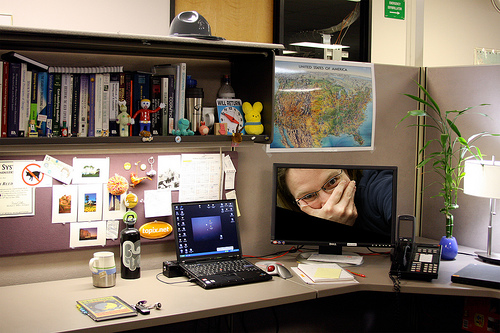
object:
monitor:
[271, 163, 397, 248]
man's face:
[286, 169, 355, 217]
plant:
[395, 77, 499, 235]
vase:
[438, 237, 458, 261]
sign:
[385, 1, 404, 20]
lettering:
[388, 2, 401, 17]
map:
[271, 56, 373, 149]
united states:
[275, 73, 373, 148]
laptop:
[171, 199, 273, 290]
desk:
[0, 27, 500, 333]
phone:
[390, 238, 442, 281]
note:
[419, 252, 435, 263]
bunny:
[242, 102, 264, 134]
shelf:
[0, 135, 243, 158]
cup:
[88, 251, 115, 287]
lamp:
[463, 159, 500, 263]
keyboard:
[182, 259, 256, 276]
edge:
[196, 267, 261, 276]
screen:
[174, 203, 236, 256]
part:
[221, 224, 226, 234]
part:
[198, 264, 206, 272]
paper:
[315, 267, 342, 278]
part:
[334, 270, 336, 272]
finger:
[325, 179, 349, 211]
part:
[331, 198, 334, 203]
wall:
[237, 61, 420, 257]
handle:
[88, 259, 97, 274]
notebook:
[297, 263, 354, 283]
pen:
[346, 269, 365, 277]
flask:
[120, 215, 141, 277]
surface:
[0, 235, 500, 333]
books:
[1, 52, 187, 136]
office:
[1, 0, 499, 332]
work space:
[0, 150, 499, 322]